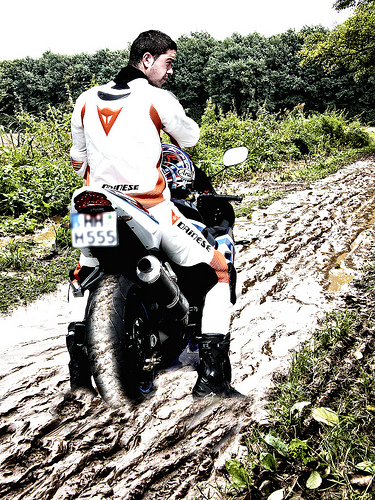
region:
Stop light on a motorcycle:
[72, 189, 111, 210]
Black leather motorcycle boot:
[191, 332, 248, 400]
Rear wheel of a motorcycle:
[89, 270, 157, 408]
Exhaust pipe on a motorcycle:
[137, 255, 191, 323]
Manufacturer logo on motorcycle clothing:
[170, 210, 211, 252]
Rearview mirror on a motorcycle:
[211, 144, 251, 179]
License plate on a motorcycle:
[70, 211, 116, 245]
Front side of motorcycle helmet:
[160, 142, 194, 206]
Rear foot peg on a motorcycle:
[68, 264, 102, 295]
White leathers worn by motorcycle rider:
[69, 77, 231, 337]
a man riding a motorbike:
[72, 12, 328, 428]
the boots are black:
[182, 326, 242, 408]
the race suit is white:
[72, 64, 287, 379]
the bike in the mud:
[27, 149, 256, 444]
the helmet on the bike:
[149, 133, 203, 229]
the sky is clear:
[47, 6, 266, 68]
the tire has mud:
[85, 276, 150, 415]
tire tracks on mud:
[246, 194, 342, 327]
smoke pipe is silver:
[124, 253, 206, 341]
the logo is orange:
[91, 98, 121, 142]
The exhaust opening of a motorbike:
[133, 255, 164, 283]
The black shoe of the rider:
[190, 332, 237, 404]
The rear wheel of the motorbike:
[85, 284, 155, 416]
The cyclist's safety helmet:
[160, 146, 196, 193]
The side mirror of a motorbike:
[221, 145, 249, 169]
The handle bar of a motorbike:
[201, 186, 246, 205]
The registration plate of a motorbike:
[70, 210, 116, 246]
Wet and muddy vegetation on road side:
[247, 325, 363, 498]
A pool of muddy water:
[328, 251, 356, 289]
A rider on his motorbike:
[68, 27, 252, 301]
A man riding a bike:
[41, 13, 265, 435]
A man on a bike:
[56, 16, 263, 446]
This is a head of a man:
[108, 13, 186, 99]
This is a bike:
[50, 126, 312, 463]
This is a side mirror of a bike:
[201, 136, 261, 193]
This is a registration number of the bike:
[67, 209, 123, 248]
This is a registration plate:
[67, 206, 118, 242]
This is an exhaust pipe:
[129, 251, 198, 332]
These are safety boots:
[190, 324, 265, 423]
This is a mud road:
[3, 176, 373, 493]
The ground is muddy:
[0, 149, 369, 480]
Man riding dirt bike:
[29, 16, 304, 448]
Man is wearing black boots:
[196, 323, 252, 410]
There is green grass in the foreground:
[309, 347, 371, 495]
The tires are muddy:
[61, 274, 183, 424]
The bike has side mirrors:
[212, 141, 250, 174]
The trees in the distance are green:
[0, 45, 371, 115]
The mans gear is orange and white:
[45, 75, 240, 420]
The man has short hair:
[127, 22, 177, 90]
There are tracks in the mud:
[6, 400, 213, 494]